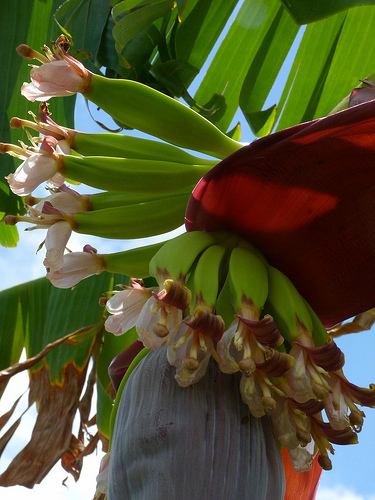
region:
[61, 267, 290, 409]
the flower is white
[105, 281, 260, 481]
the flower is white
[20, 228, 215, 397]
the flower is white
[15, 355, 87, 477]
dried banana leaves visible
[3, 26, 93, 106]
pink flower with large stamen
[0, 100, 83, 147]
pink flower with large stamen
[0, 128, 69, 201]
pink flower with large stamen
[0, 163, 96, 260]
pink flower with large stamen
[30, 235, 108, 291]
pink flower with large stamen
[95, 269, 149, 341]
pink flower with large stamen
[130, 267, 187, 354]
pink flower with large stamen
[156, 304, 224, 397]
pink flower with large stamen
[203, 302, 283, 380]
pink flower with large stamen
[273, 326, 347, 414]
pink flower with large stamen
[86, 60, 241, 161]
Stem of flower is green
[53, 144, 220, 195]
Stem of flower is green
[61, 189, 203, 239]
Stem of flower is green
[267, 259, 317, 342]
Stem of flower is green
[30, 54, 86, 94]
Flower petal is pink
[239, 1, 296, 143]
Leaf is green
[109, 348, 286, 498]
Big purple flower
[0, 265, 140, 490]
Leaf is green and brown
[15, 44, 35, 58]
Brown furry bulb on flower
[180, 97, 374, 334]
Big red flower leaf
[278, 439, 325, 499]
Orange piece to the right of a banana tree.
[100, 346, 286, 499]
Large white bottom on a banana plant.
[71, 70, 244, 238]
Top five left side unripened bananas.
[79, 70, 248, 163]
Very top flat green unripe banana.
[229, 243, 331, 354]
Three green bananas on the right bottom.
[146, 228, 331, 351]
Bottom 5 bananas on the right.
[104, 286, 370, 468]
White flowers on the bottom of the bananas.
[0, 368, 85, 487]
Dead brown leaf on the bottom left.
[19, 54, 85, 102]
Top pink and white flower on the left.